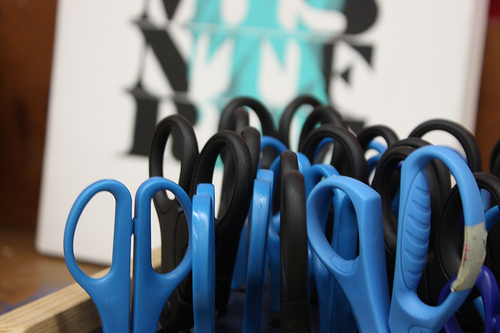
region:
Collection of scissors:
[87, 102, 489, 325]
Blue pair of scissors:
[53, 178, 186, 323]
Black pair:
[149, 120, 251, 193]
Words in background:
[131, 4, 366, 106]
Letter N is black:
[133, 22, 203, 78]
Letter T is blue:
[221, 22, 285, 96]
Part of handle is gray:
[459, 217, 489, 292]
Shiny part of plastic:
[192, 204, 207, 245]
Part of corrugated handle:
[411, 183, 431, 278]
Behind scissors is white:
[33, 0, 483, 244]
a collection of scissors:
[39, 59, 494, 324]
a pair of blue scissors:
[58, 175, 194, 326]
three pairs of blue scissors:
[68, 175, 281, 325]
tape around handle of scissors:
[310, 137, 485, 328]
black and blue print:
[119, 0, 383, 154]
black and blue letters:
[121, 0, 383, 155]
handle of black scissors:
[154, 117, 237, 210]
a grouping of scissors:
[54, 108, 414, 331]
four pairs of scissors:
[56, 174, 330, 322]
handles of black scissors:
[148, 113, 248, 210]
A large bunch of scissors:
[56, 84, 493, 330]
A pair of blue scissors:
[54, 171, 194, 330]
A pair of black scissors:
[147, 114, 250, 265]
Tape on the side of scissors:
[450, 199, 488, 313]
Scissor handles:
[293, 140, 493, 327]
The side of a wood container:
[0, 231, 197, 331]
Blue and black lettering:
[110, 0, 354, 159]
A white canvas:
[25, 0, 481, 248]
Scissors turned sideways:
[179, 149, 281, 326]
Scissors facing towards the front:
[57, 170, 195, 331]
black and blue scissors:
[37, 89, 497, 324]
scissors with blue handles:
[56, 173, 222, 328]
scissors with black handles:
[214, 87, 476, 142]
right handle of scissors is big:
[303, 143, 483, 314]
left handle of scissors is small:
[303, 173, 382, 281]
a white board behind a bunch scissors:
[30, 0, 492, 281]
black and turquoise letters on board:
[106, 0, 397, 152]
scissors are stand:
[45, 82, 495, 323]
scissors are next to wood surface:
[0, 272, 90, 327]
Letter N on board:
[116, 14, 208, 100]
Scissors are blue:
[65, 172, 194, 331]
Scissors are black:
[150, 111, 250, 272]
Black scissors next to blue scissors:
[277, 150, 315, 332]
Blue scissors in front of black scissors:
[305, 146, 481, 331]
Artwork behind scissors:
[32, 0, 485, 278]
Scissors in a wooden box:
[62, 169, 192, 331]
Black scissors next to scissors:
[222, 92, 322, 153]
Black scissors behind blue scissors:
[305, 122, 435, 236]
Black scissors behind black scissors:
[365, 119, 480, 176]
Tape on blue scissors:
[450, 210, 488, 293]